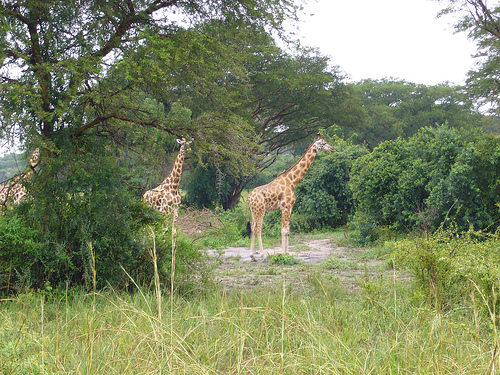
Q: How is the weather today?
A: It is clear.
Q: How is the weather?
A: It is clear.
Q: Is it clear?
A: Yes, it is clear.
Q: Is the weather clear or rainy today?
A: It is clear.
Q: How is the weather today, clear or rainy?
A: It is clear.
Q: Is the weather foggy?
A: No, it is clear.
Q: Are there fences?
A: No, there are no fences.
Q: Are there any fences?
A: No, there are no fences.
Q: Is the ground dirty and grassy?
A: Yes, the ground is dirty and grassy.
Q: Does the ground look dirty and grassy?
A: Yes, the ground is dirty and grassy.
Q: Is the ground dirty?
A: Yes, the ground is dirty.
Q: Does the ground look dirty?
A: Yes, the ground is dirty.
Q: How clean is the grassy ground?
A: The ground is dirty.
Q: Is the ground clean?
A: No, the ground is dirty.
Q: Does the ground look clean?
A: No, the ground is dirty.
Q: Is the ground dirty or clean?
A: The ground is dirty.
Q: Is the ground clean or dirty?
A: The ground is dirty.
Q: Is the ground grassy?
A: Yes, the ground is grassy.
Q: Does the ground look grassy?
A: Yes, the ground is grassy.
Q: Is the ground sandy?
A: No, the ground is grassy.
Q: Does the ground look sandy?
A: No, the ground is grassy.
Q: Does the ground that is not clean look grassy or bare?
A: The ground is grassy.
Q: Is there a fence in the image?
A: No, there are no fences.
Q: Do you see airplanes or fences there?
A: No, there are no fences or airplanes.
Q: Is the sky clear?
A: Yes, the sky is clear.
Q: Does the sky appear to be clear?
A: Yes, the sky is clear.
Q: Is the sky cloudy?
A: No, the sky is clear.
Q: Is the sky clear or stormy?
A: The sky is clear.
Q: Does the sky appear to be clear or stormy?
A: The sky is clear.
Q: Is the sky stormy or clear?
A: The sky is clear.